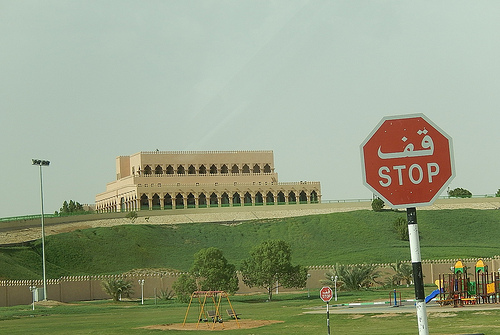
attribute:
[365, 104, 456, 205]
stop sign — white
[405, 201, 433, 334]
pole — black, white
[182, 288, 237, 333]
swing set — yellow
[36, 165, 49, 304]
pole — tall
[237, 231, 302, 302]
tree — green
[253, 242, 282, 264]
leaves — green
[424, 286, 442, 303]
slide — blue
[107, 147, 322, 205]
building — tan, two story, large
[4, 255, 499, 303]
fence — tan, wooden, tall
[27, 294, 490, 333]
grass — green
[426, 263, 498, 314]
playground equipment — for children, colorful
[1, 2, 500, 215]
sky — blue